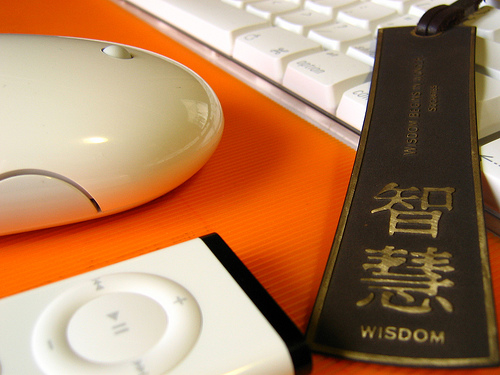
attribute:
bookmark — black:
[303, 27, 498, 370]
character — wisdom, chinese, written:
[357, 182, 455, 313]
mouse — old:
[0, 33, 225, 236]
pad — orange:
[0, 0, 499, 374]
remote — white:
[4, 231, 312, 374]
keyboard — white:
[115, 1, 500, 239]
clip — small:
[416, 0, 482, 34]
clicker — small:
[103, 44, 130, 59]